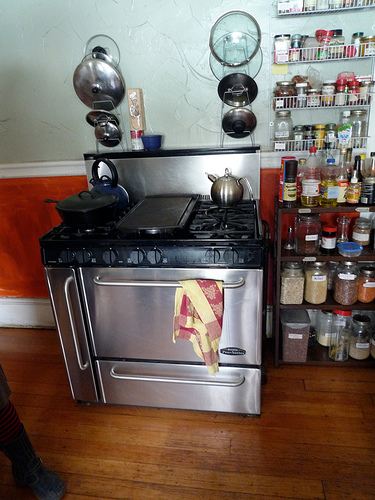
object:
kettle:
[208, 168, 243, 209]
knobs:
[129, 249, 143, 264]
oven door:
[78, 265, 263, 366]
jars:
[280, 263, 305, 305]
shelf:
[281, 255, 374, 261]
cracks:
[184, 56, 213, 85]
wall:
[0, 0, 70, 158]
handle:
[63, 275, 89, 370]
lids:
[210, 12, 261, 67]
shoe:
[5, 423, 66, 500]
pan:
[43, 190, 118, 222]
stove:
[190, 202, 255, 234]